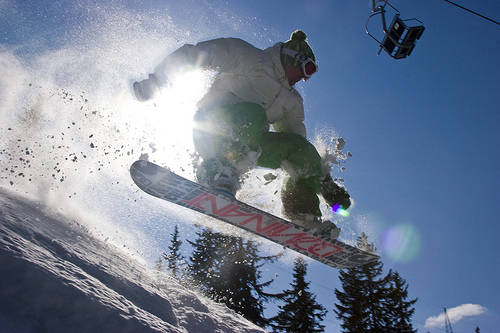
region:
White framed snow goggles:
[302, 60, 326, 77]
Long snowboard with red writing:
[130, 159, 392, 280]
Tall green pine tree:
[326, 230, 418, 331]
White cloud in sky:
[425, 296, 484, 331]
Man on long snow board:
[132, 10, 364, 234]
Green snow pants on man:
[205, 90, 327, 190]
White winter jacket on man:
[156, 28, 321, 133]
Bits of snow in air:
[7, 75, 162, 207]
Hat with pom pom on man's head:
[275, 23, 322, 63]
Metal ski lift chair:
[360, 3, 437, 64]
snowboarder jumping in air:
[122, 23, 390, 274]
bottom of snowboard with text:
[131, 158, 381, 275]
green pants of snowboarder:
[191, 101, 325, 219]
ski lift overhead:
[361, 3, 438, 68]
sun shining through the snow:
[102, 58, 212, 147]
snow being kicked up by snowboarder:
[5, 89, 164, 205]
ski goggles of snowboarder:
[282, 45, 326, 85]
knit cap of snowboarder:
[277, 26, 347, 81]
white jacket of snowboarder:
[155, 35, 351, 171]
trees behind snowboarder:
[167, 201, 427, 328]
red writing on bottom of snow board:
[186, 186, 336, 270]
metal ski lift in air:
[349, 3, 441, 68]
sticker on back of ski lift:
[381, 18, 401, 32]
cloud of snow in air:
[21, 15, 120, 199]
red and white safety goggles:
[273, 43, 326, 90]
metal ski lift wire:
[437, 0, 495, 32]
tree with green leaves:
[339, 276, 412, 325]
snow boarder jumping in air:
[121, 14, 409, 297]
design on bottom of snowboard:
[340, 248, 375, 276]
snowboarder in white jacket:
[124, 16, 361, 258]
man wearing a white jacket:
[132, 12, 367, 193]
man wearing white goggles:
[279, 20, 329, 102]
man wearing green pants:
[146, 12, 366, 241]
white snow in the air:
[11, 48, 128, 199]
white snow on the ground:
[5, 213, 150, 318]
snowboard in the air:
[144, 156, 394, 283]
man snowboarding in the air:
[136, 10, 395, 257]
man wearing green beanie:
[272, 20, 315, 75]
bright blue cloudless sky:
[363, 76, 498, 187]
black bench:
[360, 5, 428, 66]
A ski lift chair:
[364, 4, 426, 60]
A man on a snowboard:
[131, 16, 379, 268]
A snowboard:
[129, 157, 379, 272]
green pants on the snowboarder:
[191, 109, 317, 187]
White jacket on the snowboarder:
[153, 40, 308, 135]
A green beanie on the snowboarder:
[279, 30, 314, 67]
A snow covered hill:
[2, 178, 266, 332]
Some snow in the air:
[1, 39, 357, 204]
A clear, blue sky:
[5, 4, 499, 328]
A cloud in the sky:
[418, 297, 488, 332]